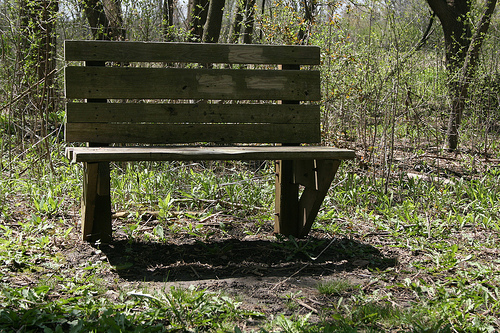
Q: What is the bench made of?
A: Wood.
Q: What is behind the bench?
A: Woods.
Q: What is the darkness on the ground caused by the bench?
A: Shadow.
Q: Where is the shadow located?
A: On the ground in front of the bench.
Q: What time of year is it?
A: Spring.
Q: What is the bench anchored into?
A: The ground.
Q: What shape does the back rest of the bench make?
A: A rectangle.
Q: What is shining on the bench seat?
A: Sun.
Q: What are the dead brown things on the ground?
A: Branches.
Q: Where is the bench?
A: In the woods.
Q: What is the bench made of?
A: Wood.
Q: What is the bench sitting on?
A: A patch of dirt.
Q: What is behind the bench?
A: Trees.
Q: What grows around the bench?
A: Green grass and weeds.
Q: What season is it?
A: Spring.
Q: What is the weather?
A: Sunny.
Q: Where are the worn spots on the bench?
A: On the top two planks of the back of the bench.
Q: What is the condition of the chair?
A: Old.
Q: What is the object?
A: Chair.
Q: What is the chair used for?
A: To sit down.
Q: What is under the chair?
A: Grass and dirt.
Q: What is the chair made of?
A: Wood.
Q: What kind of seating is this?
A: Bench.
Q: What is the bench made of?
A: Wood.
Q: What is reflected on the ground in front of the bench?
A: Shadow of bench.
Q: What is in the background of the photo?
A: Trees.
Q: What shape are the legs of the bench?
A: Triangle.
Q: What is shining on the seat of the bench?
A: Sunlight.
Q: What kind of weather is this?
A: Sunny and clear.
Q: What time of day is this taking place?
A: Daylight hours.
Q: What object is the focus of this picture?
A: A bench.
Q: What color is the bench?
A: Brown.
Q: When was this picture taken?
A: During the day.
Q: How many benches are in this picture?
A: One.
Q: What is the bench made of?
A: Wood.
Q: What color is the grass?
A: Green.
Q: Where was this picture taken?
A: In the forest.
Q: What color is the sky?
A: Blue.